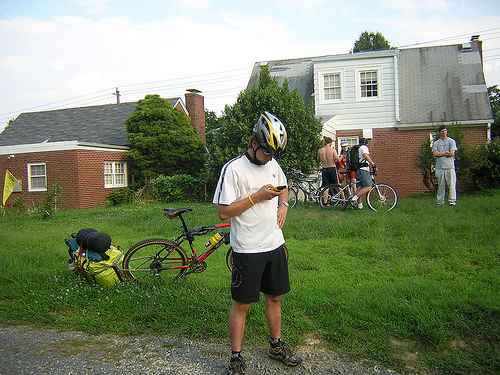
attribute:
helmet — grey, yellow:
[254, 104, 295, 162]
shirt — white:
[199, 146, 302, 252]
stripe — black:
[208, 159, 242, 213]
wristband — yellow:
[245, 193, 255, 208]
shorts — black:
[217, 257, 297, 301]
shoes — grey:
[232, 343, 294, 372]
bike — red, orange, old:
[104, 210, 291, 297]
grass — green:
[307, 197, 499, 352]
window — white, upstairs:
[302, 65, 389, 120]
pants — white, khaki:
[435, 164, 462, 210]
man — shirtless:
[317, 135, 350, 212]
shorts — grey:
[356, 165, 378, 209]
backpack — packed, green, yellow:
[62, 220, 114, 300]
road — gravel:
[0, 323, 193, 368]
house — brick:
[6, 95, 207, 199]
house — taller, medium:
[243, 48, 493, 215]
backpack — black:
[345, 142, 359, 176]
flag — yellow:
[0, 162, 26, 227]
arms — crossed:
[425, 143, 453, 167]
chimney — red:
[179, 88, 213, 170]